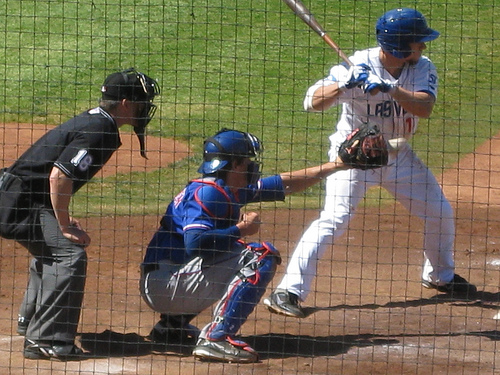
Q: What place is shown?
A: It is a field.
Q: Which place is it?
A: It is a field.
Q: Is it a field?
A: Yes, it is a field.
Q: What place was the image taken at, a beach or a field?
A: It was taken at a field.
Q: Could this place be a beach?
A: No, it is a field.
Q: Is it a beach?
A: No, it is a field.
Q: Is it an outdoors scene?
A: Yes, it is outdoors.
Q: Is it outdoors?
A: Yes, it is outdoors.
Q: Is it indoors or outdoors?
A: It is outdoors.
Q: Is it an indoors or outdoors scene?
A: It is outdoors.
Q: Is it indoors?
A: No, it is outdoors.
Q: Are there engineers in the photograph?
A: No, there are no engineers.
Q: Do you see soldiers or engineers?
A: No, there are no engineers or soldiers.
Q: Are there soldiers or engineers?
A: No, there are no engineers or soldiers.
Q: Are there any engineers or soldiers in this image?
A: No, there are no engineers or soldiers.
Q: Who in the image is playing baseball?
A: The catcher is playing baseball.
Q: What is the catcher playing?
A: The catcher is playing baseball.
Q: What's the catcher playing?
A: The catcher is playing baseball.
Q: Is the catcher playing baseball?
A: Yes, the catcher is playing baseball.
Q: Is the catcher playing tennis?
A: No, the catcher is playing baseball.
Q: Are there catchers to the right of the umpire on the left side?
A: Yes, there is a catcher to the right of the umpire.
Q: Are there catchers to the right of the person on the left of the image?
A: Yes, there is a catcher to the right of the umpire.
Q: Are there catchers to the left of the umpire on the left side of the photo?
A: No, the catcher is to the right of the umpire.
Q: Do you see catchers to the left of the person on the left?
A: No, the catcher is to the right of the umpire.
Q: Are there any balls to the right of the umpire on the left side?
A: No, there is a catcher to the right of the umpire.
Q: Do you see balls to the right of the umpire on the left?
A: No, there is a catcher to the right of the umpire.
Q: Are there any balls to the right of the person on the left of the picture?
A: No, there is a catcher to the right of the umpire.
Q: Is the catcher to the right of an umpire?
A: Yes, the catcher is to the right of an umpire.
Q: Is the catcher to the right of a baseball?
A: No, the catcher is to the right of an umpire.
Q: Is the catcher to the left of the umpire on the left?
A: No, the catcher is to the right of the umpire.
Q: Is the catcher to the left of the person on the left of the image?
A: No, the catcher is to the right of the umpire.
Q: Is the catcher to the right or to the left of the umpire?
A: The catcher is to the right of the umpire.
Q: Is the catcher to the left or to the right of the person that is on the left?
A: The catcher is to the right of the umpire.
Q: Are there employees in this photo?
A: No, there are no employees.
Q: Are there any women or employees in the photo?
A: No, there are no employees or women.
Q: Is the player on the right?
A: Yes, the player is on the right of the image.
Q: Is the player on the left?
A: No, the player is on the right of the image.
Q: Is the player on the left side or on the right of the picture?
A: The player is on the right of the image.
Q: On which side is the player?
A: The player is on the right of the image.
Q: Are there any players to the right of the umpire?
A: Yes, there is a player to the right of the umpire.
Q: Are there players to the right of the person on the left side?
A: Yes, there is a player to the right of the umpire.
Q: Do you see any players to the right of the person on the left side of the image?
A: Yes, there is a player to the right of the umpire.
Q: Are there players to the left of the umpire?
A: No, the player is to the right of the umpire.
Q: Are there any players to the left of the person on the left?
A: No, the player is to the right of the umpire.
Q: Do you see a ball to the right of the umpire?
A: No, there is a player to the right of the umpire.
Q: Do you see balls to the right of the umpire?
A: No, there is a player to the right of the umpire.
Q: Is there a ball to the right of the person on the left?
A: No, there is a player to the right of the umpire.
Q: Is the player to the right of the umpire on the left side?
A: Yes, the player is to the right of the umpire.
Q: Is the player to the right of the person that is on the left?
A: Yes, the player is to the right of the umpire.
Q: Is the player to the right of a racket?
A: No, the player is to the right of the umpire.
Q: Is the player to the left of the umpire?
A: No, the player is to the right of the umpire.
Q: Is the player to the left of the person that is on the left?
A: No, the player is to the right of the umpire.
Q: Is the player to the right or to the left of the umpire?
A: The player is to the right of the umpire.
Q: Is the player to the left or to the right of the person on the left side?
A: The player is to the right of the umpire.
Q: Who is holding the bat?
A: The player is holding the bat.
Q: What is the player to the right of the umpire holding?
A: The player is holding the bat.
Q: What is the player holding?
A: The player is holding the bat.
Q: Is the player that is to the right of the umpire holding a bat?
A: Yes, the player is holding a bat.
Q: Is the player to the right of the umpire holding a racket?
A: No, the player is holding a bat.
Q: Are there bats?
A: Yes, there is a bat.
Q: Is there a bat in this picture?
A: Yes, there is a bat.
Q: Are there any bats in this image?
A: Yes, there is a bat.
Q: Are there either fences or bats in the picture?
A: Yes, there is a bat.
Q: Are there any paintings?
A: No, there are no paintings.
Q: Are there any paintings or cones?
A: No, there are no paintings or cones.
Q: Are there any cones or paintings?
A: No, there are no paintings or cones.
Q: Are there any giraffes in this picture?
A: No, there are no giraffes.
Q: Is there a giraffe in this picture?
A: No, there are no giraffes.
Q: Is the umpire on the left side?
A: Yes, the umpire is on the left of the image.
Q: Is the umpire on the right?
A: No, the umpire is on the left of the image.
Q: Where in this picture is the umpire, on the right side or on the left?
A: The umpire is on the left of the image.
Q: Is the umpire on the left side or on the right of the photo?
A: The umpire is on the left of the image.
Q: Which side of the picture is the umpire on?
A: The umpire is on the left of the image.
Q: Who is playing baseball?
A: The umpire is playing baseball.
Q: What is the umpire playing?
A: The umpire is playing baseball.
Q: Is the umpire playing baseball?
A: Yes, the umpire is playing baseball.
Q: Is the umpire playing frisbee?
A: No, the umpire is playing baseball.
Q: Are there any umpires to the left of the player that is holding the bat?
A: Yes, there is an umpire to the left of the player.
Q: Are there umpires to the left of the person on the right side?
A: Yes, there is an umpire to the left of the player.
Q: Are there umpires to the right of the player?
A: No, the umpire is to the left of the player.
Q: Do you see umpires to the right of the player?
A: No, the umpire is to the left of the player.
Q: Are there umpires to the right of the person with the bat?
A: No, the umpire is to the left of the player.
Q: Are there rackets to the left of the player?
A: No, there is an umpire to the left of the player.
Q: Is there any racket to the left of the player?
A: No, there is an umpire to the left of the player.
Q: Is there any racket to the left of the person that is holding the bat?
A: No, there is an umpire to the left of the player.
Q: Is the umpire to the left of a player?
A: Yes, the umpire is to the left of a player.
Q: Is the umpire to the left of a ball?
A: No, the umpire is to the left of a player.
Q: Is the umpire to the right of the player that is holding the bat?
A: No, the umpire is to the left of the player.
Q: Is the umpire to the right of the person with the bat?
A: No, the umpire is to the left of the player.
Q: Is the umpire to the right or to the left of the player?
A: The umpire is to the left of the player.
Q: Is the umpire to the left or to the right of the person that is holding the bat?
A: The umpire is to the left of the player.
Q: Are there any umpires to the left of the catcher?
A: Yes, there is an umpire to the left of the catcher.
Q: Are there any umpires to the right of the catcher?
A: No, the umpire is to the left of the catcher.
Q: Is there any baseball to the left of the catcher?
A: No, there is an umpire to the left of the catcher.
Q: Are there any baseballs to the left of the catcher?
A: No, there is an umpire to the left of the catcher.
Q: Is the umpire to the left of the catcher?
A: Yes, the umpire is to the left of the catcher.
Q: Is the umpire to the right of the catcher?
A: No, the umpire is to the left of the catcher.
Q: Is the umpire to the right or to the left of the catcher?
A: The umpire is to the left of the catcher.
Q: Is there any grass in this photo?
A: Yes, there is grass.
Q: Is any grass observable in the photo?
A: Yes, there is grass.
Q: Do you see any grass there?
A: Yes, there is grass.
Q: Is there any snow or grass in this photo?
A: Yes, there is grass.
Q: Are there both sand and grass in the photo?
A: No, there is grass but no sand.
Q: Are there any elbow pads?
A: No, there are no elbow pads.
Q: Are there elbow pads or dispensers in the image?
A: No, there are no elbow pads or dispensers.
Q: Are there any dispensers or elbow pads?
A: No, there are no elbow pads or dispensers.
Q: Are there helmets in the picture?
A: Yes, there is a helmet.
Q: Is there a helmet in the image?
A: Yes, there is a helmet.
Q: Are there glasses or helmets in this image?
A: Yes, there is a helmet.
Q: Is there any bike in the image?
A: No, there are no bikes.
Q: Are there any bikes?
A: No, there are no bikes.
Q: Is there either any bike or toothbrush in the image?
A: No, there are no bikes or toothbrushes.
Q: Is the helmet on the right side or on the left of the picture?
A: The helmet is on the right of the image.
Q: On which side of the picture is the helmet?
A: The helmet is on the right of the image.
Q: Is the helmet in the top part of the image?
A: Yes, the helmet is in the top of the image.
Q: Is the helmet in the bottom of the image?
A: No, the helmet is in the top of the image.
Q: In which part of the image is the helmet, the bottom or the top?
A: The helmet is in the top of the image.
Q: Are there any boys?
A: No, there are no boys.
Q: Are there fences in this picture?
A: Yes, there is a fence.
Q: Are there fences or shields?
A: Yes, there is a fence.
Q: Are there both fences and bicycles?
A: No, there is a fence but no bikes.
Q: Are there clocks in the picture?
A: No, there are no clocks.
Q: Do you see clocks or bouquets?
A: No, there are no clocks or bouquets.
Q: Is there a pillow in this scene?
A: No, there are no pillows.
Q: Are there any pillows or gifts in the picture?
A: No, there are no pillows or gifts.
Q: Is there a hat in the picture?
A: Yes, there is a hat.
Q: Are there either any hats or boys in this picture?
A: Yes, there is a hat.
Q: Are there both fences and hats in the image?
A: Yes, there are both a hat and a fence.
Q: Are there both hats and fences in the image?
A: Yes, there are both a hat and a fence.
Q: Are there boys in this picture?
A: No, there are no boys.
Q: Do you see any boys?
A: No, there are no boys.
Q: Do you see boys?
A: No, there are no boys.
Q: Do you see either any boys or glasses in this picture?
A: No, there are no boys or glasses.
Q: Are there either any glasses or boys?
A: No, there are no boys or glasses.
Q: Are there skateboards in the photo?
A: No, there are no skateboards.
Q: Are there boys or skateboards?
A: No, there are no skateboards or boys.